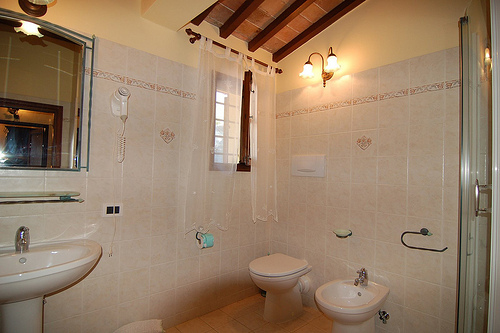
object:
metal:
[398, 227, 451, 255]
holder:
[396, 222, 451, 255]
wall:
[395, 127, 450, 208]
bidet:
[311, 271, 392, 324]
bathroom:
[0, 0, 499, 332]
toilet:
[240, 242, 313, 325]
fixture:
[299, 49, 335, 90]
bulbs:
[297, 55, 325, 82]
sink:
[1, 210, 109, 333]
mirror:
[0, 8, 98, 172]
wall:
[100, 35, 144, 81]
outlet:
[99, 200, 127, 221]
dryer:
[104, 80, 137, 165]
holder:
[327, 223, 355, 242]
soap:
[331, 226, 353, 238]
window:
[206, 76, 258, 171]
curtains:
[246, 59, 283, 224]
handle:
[466, 175, 495, 219]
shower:
[443, 4, 498, 333]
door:
[447, 11, 496, 333]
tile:
[371, 153, 411, 188]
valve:
[377, 310, 394, 327]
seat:
[245, 249, 310, 282]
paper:
[193, 233, 218, 251]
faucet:
[12, 221, 38, 257]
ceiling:
[174, 1, 386, 66]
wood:
[231, 70, 257, 174]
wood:
[247, 2, 310, 50]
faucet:
[350, 263, 372, 295]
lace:
[252, 62, 287, 223]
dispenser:
[191, 230, 220, 251]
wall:
[153, 226, 188, 261]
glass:
[470, 44, 493, 175]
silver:
[471, 175, 481, 218]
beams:
[218, 0, 267, 40]